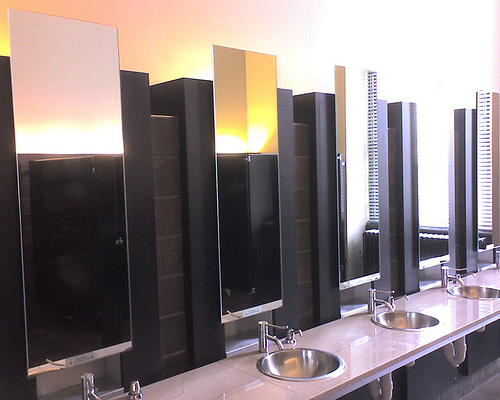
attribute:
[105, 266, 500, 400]
counter — white, shiny, sink counter, granite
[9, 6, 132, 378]
mirror — huge, nice, bathroom mirror, long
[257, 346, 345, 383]
sink — silver, bowl shaped, bathroom sink, round, steel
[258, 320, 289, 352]
faucet — silver, stainless, steel, fixture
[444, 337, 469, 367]
pipe — pvc, white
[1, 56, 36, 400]
wall — black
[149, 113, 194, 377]
wall — tiled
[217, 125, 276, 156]
reflection — light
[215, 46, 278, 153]
effect — yellow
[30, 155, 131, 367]
door — reflected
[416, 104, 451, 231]
window — reflection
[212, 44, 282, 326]
mirror — huge, nice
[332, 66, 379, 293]
mirror — huge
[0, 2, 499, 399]
scene — bathroom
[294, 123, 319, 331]
panel — black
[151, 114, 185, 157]
brick — brown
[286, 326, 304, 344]
despenser — silver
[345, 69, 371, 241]
sunlight — reflected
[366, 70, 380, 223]
blinds — reflected